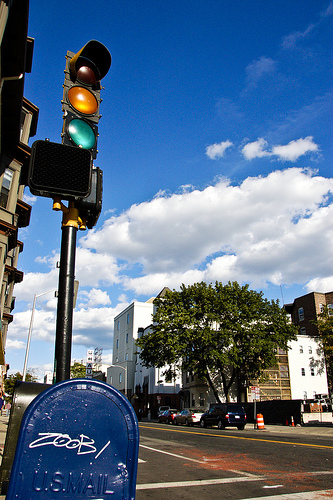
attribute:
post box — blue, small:
[5, 380, 137, 497]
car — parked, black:
[197, 404, 248, 429]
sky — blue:
[17, 2, 332, 376]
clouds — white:
[12, 135, 329, 354]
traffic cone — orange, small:
[256, 410, 266, 433]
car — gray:
[174, 408, 204, 427]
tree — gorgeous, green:
[142, 281, 294, 426]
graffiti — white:
[29, 430, 111, 462]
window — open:
[2, 163, 16, 210]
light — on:
[62, 41, 109, 151]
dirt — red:
[165, 444, 332, 497]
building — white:
[108, 300, 157, 391]